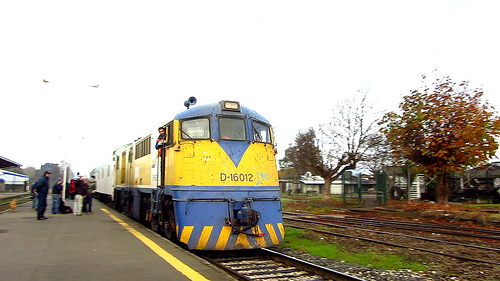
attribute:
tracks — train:
[202, 233, 372, 275]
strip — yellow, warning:
[91, 195, 196, 278]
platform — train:
[0, 131, 213, 279]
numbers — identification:
[212, 162, 264, 187]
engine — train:
[97, 78, 307, 252]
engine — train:
[86, 83, 315, 264]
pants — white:
[65, 189, 83, 219]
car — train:
[82, 103, 329, 273]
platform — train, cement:
[5, 182, 228, 278]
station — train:
[0, 149, 237, 247]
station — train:
[2, 151, 239, 278]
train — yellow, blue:
[100, 85, 322, 266]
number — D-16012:
[211, 165, 265, 190]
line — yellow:
[89, 192, 213, 279]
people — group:
[5, 155, 114, 227]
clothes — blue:
[27, 158, 57, 214]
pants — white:
[68, 183, 86, 215]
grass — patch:
[282, 214, 448, 277]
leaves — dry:
[378, 65, 489, 162]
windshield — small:
[181, 105, 217, 144]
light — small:
[216, 90, 246, 116]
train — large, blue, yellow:
[56, 86, 305, 276]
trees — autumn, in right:
[363, 53, 490, 208]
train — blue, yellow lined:
[88, 93, 284, 251]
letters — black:
[220, 172, 253, 182]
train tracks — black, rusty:
[198, 248, 358, 279]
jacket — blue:
[32, 176, 49, 191]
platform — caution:
[4, 197, 234, 278]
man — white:
[72, 176, 82, 214]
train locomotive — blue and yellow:
[112, 93, 286, 252]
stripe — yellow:
[100, 207, 204, 279]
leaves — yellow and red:
[377, 76, 498, 170]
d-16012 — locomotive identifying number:
[221, 171, 254, 182]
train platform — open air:
[2, 194, 234, 279]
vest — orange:
[158, 135, 163, 153]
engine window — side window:
[158, 121, 168, 187]